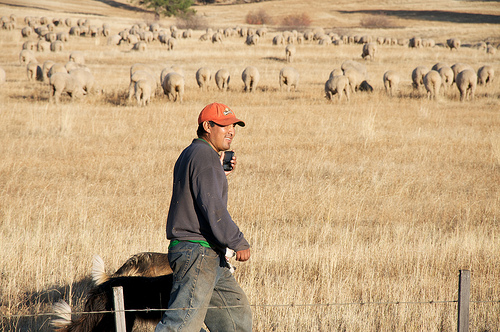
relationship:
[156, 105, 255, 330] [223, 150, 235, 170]
farmer has cellphone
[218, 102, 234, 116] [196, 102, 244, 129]
symbol on red cap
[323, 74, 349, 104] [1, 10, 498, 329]
elephants in field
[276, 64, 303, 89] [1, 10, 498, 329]
elephants in field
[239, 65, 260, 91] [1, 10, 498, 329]
elephants in field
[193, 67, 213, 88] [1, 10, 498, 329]
elephants in field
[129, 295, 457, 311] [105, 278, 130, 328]
barbed wire between fence posts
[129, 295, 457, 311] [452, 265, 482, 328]
barbed wire between fence posts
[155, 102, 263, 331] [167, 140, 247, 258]
man wearing sweatshirt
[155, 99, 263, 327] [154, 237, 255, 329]
man wearing jeans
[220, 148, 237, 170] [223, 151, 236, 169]
cellphone in hand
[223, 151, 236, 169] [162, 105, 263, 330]
hand of man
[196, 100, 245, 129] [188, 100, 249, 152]
red cap on man's head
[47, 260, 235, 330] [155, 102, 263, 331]
sheepdog with man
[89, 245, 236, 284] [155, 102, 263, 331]
sheepdog with man